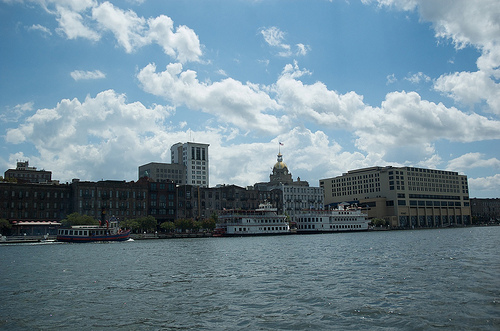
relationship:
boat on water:
[58, 217, 131, 240] [0, 223, 499, 329]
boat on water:
[53, 220, 133, 244] [0, 223, 499, 329]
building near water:
[3, 182, 76, 239] [0, 223, 499, 329]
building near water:
[71, 181, 145, 231] [0, 223, 499, 329]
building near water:
[143, 174, 182, 234] [0, 223, 499, 329]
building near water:
[170, 140, 209, 188] [0, 223, 499, 329]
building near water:
[317, 163, 475, 229] [0, 223, 499, 329]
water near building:
[0, 223, 499, 329] [318, 165, 472, 225]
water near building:
[0, 223, 499, 329] [255, 181, 331, 231]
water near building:
[0, 223, 499, 329] [168, 140, 211, 190]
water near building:
[0, 223, 499, 329] [135, 162, 185, 188]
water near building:
[0, 223, 499, 329] [3, 176, 72, 236]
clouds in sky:
[0, 0, 498, 199] [0, 0, 498, 200]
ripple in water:
[0, 224, 499, 331] [0, 223, 499, 329]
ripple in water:
[367, 258, 427, 296] [0, 223, 499, 329]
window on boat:
[73, 230, 89, 238] [52, 222, 132, 242]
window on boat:
[62, 230, 67, 235] [55, 221, 137, 241]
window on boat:
[75, 230, 80, 240] [53, 219, 130, 243]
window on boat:
[81, 230, 89, 237] [52, 222, 132, 242]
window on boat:
[81, 230, 89, 237] [47, 224, 134, 240]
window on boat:
[93, 233, 105, 240] [47, 224, 134, 240]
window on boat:
[102, 230, 112, 237] [54, 219, 133, 245]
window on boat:
[109, 223, 115, 227] [56, 224, 132, 243]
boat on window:
[53, 220, 133, 244] [115, 221, 119, 227]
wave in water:
[0, 226, 498, 330] [0, 223, 499, 329]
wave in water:
[349, 257, 393, 283] [0, 223, 499, 329]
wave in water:
[0, 226, 498, 330] [0, 188, 494, 331]